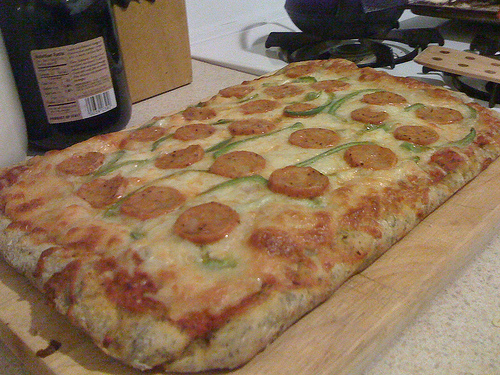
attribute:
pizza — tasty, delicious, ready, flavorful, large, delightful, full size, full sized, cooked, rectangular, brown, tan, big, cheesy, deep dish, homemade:
[1, 57, 499, 375]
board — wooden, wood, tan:
[1, 157, 500, 373]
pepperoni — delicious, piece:
[174, 202, 241, 246]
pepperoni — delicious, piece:
[266, 165, 331, 201]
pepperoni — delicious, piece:
[344, 144, 399, 171]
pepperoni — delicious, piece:
[393, 126, 439, 146]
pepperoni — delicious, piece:
[415, 105, 465, 126]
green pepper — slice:
[104, 168, 210, 218]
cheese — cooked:
[3, 59, 500, 323]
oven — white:
[184, 1, 499, 113]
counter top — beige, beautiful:
[0, 57, 499, 374]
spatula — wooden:
[413, 45, 500, 84]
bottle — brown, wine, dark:
[1, 1, 131, 153]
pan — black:
[284, 1, 409, 38]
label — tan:
[28, 35, 117, 125]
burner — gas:
[265, 25, 444, 73]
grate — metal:
[265, 27, 445, 70]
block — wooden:
[110, 0, 193, 105]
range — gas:
[185, 0, 500, 108]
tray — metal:
[405, 1, 499, 24]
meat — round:
[123, 185, 186, 221]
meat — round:
[208, 151, 267, 180]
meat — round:
[288, 127, 340, 149]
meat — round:
[228, 117, 275, 136]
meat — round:
[173, 123, 216, 142]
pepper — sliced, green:
[284, 90, 335, 118]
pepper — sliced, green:
[292, 141, 378, 169]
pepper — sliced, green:
[90, 150, 126, 176]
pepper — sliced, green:
[464, 102, 479, 121]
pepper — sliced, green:
[288, 75, 317, 84]